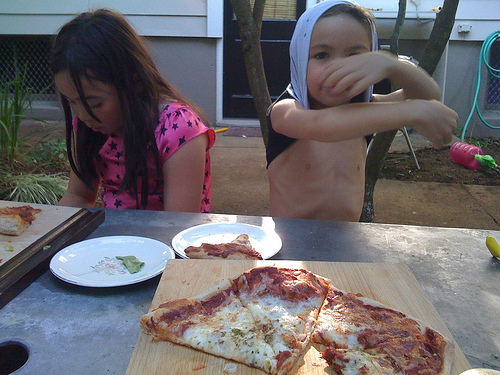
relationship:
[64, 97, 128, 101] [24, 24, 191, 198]
eyes have girl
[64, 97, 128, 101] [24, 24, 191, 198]
eyes has girl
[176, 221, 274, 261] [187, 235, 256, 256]
plate has a pizza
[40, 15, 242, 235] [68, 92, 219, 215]
girl wearing shirt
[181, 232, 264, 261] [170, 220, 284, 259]
pizza lying on plate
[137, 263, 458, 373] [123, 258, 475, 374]
pizza on board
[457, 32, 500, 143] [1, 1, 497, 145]
hose next to house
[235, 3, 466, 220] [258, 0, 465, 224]
tree behind boy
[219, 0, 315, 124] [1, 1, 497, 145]
door on house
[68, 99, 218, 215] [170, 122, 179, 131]
shirt with star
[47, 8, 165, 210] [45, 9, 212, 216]
hair on girl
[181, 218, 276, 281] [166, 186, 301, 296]
pizza on plate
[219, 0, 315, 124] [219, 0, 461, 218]
door behind tree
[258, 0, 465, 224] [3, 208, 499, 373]
boy sitting at table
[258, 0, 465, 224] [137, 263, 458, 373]
boy eating pizza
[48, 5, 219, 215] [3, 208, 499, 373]
girl sitting at table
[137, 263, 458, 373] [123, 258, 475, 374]
pizza sitting on board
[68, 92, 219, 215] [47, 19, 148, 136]
shirt over head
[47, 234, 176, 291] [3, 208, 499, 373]
white plate on table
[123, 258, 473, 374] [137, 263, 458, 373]
board beneath pizza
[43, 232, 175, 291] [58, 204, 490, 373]
white plate sitting on table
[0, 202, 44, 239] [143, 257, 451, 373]
pizza laying on board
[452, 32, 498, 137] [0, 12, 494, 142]
hose hanging on side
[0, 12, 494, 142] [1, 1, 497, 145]
side of house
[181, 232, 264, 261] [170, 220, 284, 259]
pizza on plate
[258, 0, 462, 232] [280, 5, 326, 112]
boy has shirt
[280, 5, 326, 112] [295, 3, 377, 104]
shirt on head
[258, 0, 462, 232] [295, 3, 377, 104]
boy has head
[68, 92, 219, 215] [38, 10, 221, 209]
shirt on girl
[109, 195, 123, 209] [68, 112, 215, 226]
star on shirt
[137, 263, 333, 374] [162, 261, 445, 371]
pizza slice of pizza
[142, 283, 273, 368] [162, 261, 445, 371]
pizza slice of pizza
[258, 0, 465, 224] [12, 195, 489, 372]
boy at table